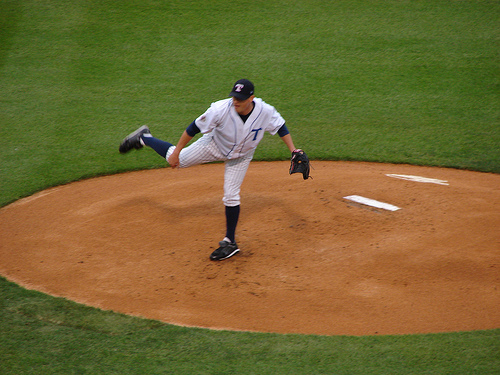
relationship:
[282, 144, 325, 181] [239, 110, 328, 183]
glove on hand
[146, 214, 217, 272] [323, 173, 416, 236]
dirt on plate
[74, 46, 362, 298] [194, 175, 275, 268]
pitcher has leg